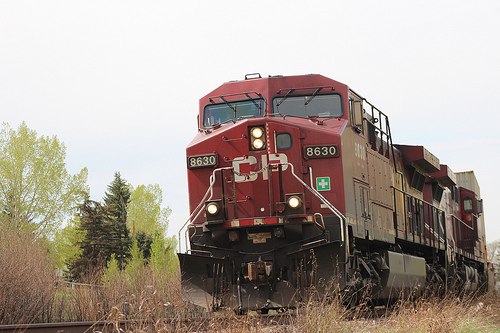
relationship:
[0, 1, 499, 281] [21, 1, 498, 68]
clouds in sky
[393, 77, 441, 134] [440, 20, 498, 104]
clouds in sky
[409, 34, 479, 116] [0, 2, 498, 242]
clouds in sky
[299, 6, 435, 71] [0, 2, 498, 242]
cloud in sky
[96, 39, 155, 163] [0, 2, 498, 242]
clouds in sky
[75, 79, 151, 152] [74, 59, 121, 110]
clound in sky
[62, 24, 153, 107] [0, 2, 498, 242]
clouds in sky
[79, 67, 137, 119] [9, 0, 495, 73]
clouds in sky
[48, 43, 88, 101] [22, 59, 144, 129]
cloud in sky